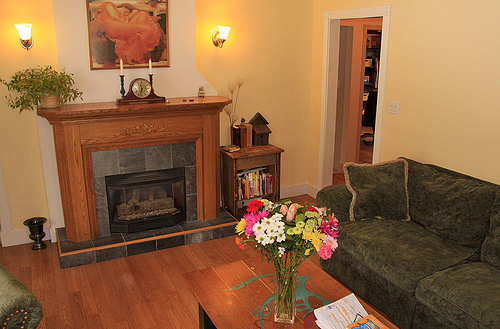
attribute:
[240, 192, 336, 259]
flowers — colorful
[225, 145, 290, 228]
shelf — wooden, brown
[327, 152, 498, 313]
couch — green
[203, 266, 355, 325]
table — wooden